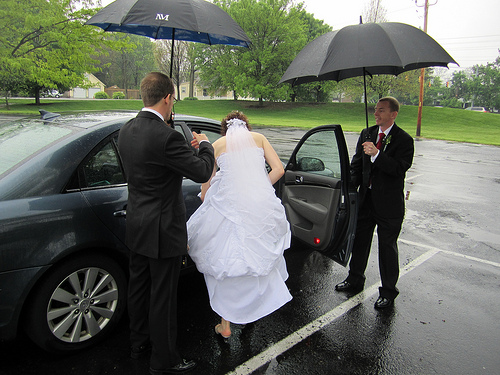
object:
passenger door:
[78, 115, 192, 293]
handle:
[114, 209, 128, 217]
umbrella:
[276, 12, 454, 103]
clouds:
[306, 0, 499, 24]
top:
[276, 21, 458, 85]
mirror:
[297, 160, 322, 170]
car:
[8, 102, 396, 344]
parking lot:
[266, 118, 497, 374]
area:
[12, 83, 498, 156]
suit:
[349, 122, 433, 309]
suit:
[116, 108, 214, 364]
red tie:
[374, 132, 386, 151]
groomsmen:
[116, 54, 415, 344]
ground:
[446, 142, 475, 184]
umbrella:
[82, 0, 247, 81]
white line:
[172, 255, 477, 372]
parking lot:
[425, 145, 492, 361]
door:
[241, 104, 369, 286]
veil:
[223, 116, 275, 223]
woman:
[186, 109, 293, 342]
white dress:
[187, 146, 292, 326]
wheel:
[25, 251, 132, 354]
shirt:
[369, 122, 395, 164]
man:
[114, 68, 216, 371]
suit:
[116, 109, 215, 261]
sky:
[321, 8, 360, 28]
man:
[330, 57, 448, 298]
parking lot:
[0, 112, 499, 372]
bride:
[184, 116, 293, 346]